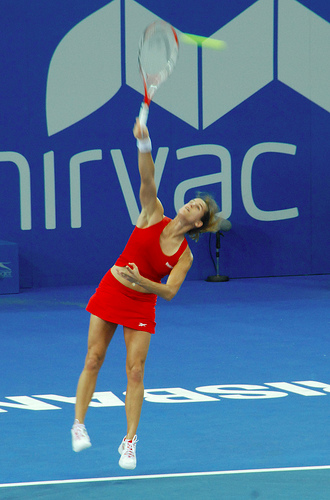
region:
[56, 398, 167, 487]
Both feet off the ground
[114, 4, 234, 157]
Racket hitting the ball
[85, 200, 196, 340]
Wearing a red tennis outfit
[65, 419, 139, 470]
White tennis shoes with a little red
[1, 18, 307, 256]
Advertisement in the background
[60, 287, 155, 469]
Her legs are very toned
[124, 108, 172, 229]
She has muscular arms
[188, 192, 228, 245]
Hair tied up in the back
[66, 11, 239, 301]
Righthanded tennis player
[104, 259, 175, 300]
Her midriff is showing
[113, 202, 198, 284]
woman's shirt is red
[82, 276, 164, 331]
woman's skirt is red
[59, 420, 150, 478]
woman's shoes are white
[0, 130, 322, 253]
letters on wall are white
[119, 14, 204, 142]
woman holding a racket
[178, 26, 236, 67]
tennis ball next to racket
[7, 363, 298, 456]
white letters on the wall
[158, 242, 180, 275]
white symbol on woman's shirt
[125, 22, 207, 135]
racket is red and white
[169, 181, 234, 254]
woman is looking upwards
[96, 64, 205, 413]
A girl playing tennis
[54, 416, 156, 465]
White tennis shoes in the air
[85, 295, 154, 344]
A red tennis skirt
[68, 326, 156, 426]
Tan and muscular legs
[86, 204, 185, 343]
A red tennis outfit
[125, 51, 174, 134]
A tennis racket in the air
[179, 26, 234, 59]
A tennis ball in motion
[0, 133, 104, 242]
A blue and white background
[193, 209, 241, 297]
Some type of microphone on a stand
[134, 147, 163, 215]
Muscular arms of an athlete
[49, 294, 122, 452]
leg of a person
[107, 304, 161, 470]
leg of a person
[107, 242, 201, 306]
arm of a person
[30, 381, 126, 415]
white letter painted on the ground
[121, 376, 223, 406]
white letter painted on the ground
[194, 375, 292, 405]
white letter painted on the ground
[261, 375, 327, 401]
white letter painted on the ground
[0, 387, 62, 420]
white letter painted on the ground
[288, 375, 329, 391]
white letter painted on the ground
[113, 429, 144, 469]
white and red shoe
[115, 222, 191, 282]
a red sports top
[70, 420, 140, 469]
a pair of white and red tennis shoes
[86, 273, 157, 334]
a red tennis skirt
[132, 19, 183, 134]
a red tennis rachet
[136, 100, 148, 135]
a white taped handle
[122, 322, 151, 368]
a woman's thigh muscle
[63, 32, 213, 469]
a woman hitting a tennis ball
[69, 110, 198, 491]
a tennis woman in the air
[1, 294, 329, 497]
a light blue tennis court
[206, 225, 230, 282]
a short black microphone stand